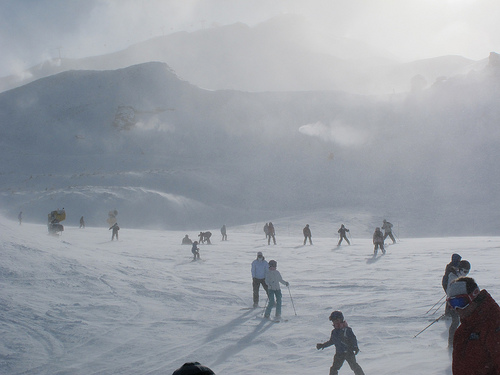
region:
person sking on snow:
[368, 227, 387, 255]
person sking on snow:
[379, 217, 398, 244]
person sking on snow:
[332, 221, 352, 251]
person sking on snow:
[302, 223, 314, 248]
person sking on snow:
[266, 221, 278, 247]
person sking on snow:
[312, 309, 368, 373]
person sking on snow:
[260, 261, 292, 322]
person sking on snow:
[247, 250, 273, 316]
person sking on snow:
[190, 241, 204, 261]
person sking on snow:
[107, 222, 120, 241]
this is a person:
[302, 301, 379, 372]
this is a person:
[435, 285, 490, 372]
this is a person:
[422, 243, 478, 325]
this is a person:
[345, 225, 400, 275]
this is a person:
[370, 200, 423, 273]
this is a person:
[234, 248, 289, 308]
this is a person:
[97, 205, 158, 256]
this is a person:
[204, 204, 244, 259]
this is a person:
[257, 219, 283, 254]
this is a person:
[20, 198, 90, 261]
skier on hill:
[250, 241, 300, 310]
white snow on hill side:
[26, 33, 92, 93]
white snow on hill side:
[312, 68, 364, 99]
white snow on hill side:
[364, 17, 395, 47]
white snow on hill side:
[448, 5, 486, 66]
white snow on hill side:
[109, 6, 151, 37]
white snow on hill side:
[262, 33, 293, 69]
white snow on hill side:
[148, 25, 208, 66]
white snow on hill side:
[70, 24, 128, 89]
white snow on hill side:
[140, 14, 186, 50]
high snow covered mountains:
[2, 8, 499, 233]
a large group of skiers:
[16, 206, 494, 373]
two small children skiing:
[189, 231, 206, 259]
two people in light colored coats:
[249, 250, 293, 322]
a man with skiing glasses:
[445, 275, 499, 373]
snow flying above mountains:
[1, 0, 498, 145]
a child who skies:
[316, 309, 368, 374]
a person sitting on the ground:
[179, 231, 194, 246]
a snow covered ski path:
[1, 218, 386, 369]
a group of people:
[256, 215, 400, 255]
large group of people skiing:
[26, 190, 493, 373]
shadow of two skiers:
[202, 312, 262, 367]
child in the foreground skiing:
[307, 307, 369, 374]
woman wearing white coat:
[265, 258, 291, 318]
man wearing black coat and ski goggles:
[442, 280, 496, 374]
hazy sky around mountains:
[9, 13, 499, 221]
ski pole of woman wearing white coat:
[285, 281, 305, 321]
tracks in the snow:
[22, 234, 445, 374]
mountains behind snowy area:
[9, 19, 499, 238]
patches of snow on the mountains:
[37, 80, 401, 210]